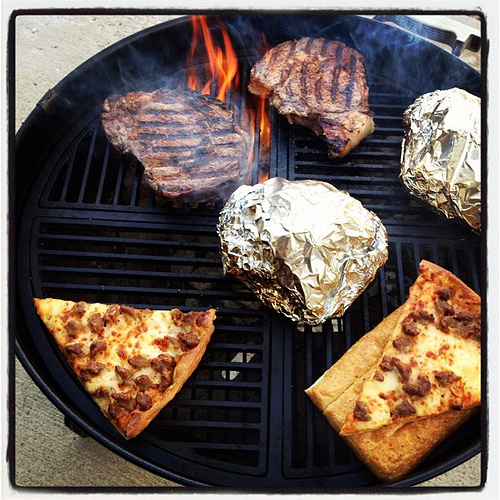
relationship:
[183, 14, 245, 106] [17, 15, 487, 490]
fire coming out of grill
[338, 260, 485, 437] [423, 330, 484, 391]
pizza with cheese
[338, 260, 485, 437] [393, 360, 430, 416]
pizza with sausage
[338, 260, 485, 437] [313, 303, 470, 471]
pizza on breadsticks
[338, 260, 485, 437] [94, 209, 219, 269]
pizza on grill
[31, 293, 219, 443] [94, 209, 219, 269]
pizza on grill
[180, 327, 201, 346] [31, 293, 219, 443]
sausage on pizza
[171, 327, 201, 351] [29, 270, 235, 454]
sausage on pizza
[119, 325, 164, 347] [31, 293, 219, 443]
cheese on pizza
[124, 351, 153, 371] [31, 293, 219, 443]
sausage on pizza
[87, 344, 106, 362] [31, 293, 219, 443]
sausage on pizza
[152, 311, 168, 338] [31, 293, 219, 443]
cheese melted on pizza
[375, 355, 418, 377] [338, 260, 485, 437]
sausage on pizza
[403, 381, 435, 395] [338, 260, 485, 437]
sausage on pizza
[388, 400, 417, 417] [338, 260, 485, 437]
sausage on pizza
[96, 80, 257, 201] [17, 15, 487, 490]
barbeque on grill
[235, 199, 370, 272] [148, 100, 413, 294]
potato on grill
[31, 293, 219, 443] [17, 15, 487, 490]
pizza on grill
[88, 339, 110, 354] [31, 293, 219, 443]
topping on pizza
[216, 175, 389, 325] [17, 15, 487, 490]
potato on grill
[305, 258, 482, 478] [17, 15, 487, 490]
breadsticks on grill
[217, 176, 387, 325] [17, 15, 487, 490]
foil on grill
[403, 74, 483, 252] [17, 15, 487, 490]
foil on grill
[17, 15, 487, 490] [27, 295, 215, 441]
grill cooking breadsticks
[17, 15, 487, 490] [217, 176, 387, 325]
grill cooking foil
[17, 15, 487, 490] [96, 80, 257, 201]
grill cooking barbeque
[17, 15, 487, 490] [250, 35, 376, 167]
grill cooking food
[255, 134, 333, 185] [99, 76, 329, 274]
metal grill cooking food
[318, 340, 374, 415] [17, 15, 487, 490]
breadsticks on grill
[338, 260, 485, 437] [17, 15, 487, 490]
pizza on grill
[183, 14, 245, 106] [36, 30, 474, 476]
fire coming out of grill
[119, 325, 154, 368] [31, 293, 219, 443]
cheese on pizza